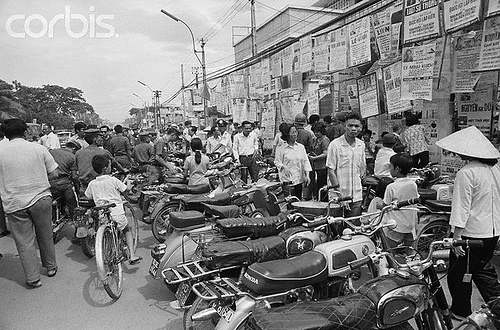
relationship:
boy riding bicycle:
[84, 154, 144, 263] [91, 194, 140, 296]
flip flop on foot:
[128, 248, 145, 272] [128, 253, 141, 266]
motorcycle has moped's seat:
[152, 192, 356, 289] [215, 215, 285, 239]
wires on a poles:
[154, 0, 259, 97] [123, 12, 208, 127]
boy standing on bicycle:
[84, 154, 144, 263] [68, 192, 145, 300]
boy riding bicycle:
[84, 154, 144, 263] [80, 187, 141, 300]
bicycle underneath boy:
[89, 196, 139, 299] [84, 154, 144, 263]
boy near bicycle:
[32, 121, 94, 228] [71, 192, 155, 299]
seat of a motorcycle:
[236, 244, 332, 296] [183, 197, 423, 326]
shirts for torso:
[266, 142, 379, 207] [326, 138, 371, 208]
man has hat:
[440, 142, 498, 322] [431, 127, 497, 160]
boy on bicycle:
[84, 154, 144, 263] [93, 180, 138, 300]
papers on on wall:
[310, 15, 377, 75] [301, 22, 413, 97]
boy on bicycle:
[84, 154, 144, 263] [88, 180, 139, 300]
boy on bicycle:
[84, 154, 144, 263] [87, 191, 144, 303]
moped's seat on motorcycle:
[201, 236, 287, 267] [160, 195, 352, 327]